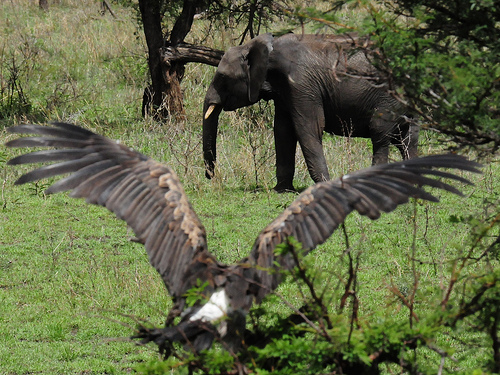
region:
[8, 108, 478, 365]
a bird in a tree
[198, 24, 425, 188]
a elephant in the grass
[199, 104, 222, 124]
a white tusk on a elephant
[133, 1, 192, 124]
a grayish brown tree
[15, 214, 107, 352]
green grass on the ground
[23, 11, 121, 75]
brown and white weeds in on the ground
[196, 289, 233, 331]
white feathers on a bird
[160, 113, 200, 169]
died bushes growing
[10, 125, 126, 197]
black feathers on a bird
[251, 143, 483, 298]
the right wing on a bird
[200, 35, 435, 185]
An elephant in the wild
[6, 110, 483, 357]
A hawk flying through the air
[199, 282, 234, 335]
The white back of a hawk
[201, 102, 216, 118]
An elephant's tusk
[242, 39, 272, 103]
An elephant's ear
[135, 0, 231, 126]
A tree trunk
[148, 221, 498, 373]
Tree branches by the hawk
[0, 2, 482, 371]
Grass in the clearing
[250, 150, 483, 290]
The wing of a hawk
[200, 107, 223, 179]
The trunk of an elephant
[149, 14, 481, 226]
an elephant is walking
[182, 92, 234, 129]
the elephant has tusks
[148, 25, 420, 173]
the elephant is big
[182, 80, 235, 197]
the trunk is long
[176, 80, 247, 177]
the trunk is thick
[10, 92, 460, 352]
the birds wings are up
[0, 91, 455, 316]
the bird is dark colored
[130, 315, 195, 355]
the tail is black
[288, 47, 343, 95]
the skin is wrinkled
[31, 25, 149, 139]
the grass is high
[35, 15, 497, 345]
An elephant is walking around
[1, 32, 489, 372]
A bird is afraid of the elephant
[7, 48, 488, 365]
A bird has spread out its wings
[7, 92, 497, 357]
A bird is preparing to take off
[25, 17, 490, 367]
An elephant is looking for food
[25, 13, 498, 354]
The animals are out in the jungle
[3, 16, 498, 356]
The bird is hunting for prey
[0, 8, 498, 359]
The bird has a long wingspan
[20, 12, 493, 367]
The animals are out in the daytime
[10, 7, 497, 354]
The animals are enjoying the day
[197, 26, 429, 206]
gray elephant in a field in the wild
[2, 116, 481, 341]
large predator bird standing in a field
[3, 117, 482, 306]
outstretched wings of a predator bird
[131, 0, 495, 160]
large tree with a broken branch laying on the ground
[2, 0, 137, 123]
overgrown brush in the background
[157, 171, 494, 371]
overgrown brush in the foreground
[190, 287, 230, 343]
white tail feathers of a predator bird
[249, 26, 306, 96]
left ear of an elephant in a field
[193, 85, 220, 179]
trunk of an elephant in a field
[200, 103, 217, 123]
tusk of an elephant in a field